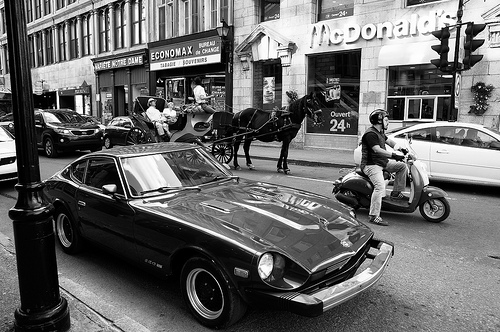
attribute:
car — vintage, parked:
[39, 140, 393, 328]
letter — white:
[330, 27, 343, 44]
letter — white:
[309, 25, 333, 49]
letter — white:
[343, 22, 360, 42]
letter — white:
[376, 21, 395, 41]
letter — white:
[392, 12, 420, 39]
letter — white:
[354, 18, 375, 42]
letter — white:
[180, 43, 195, 61]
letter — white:
[170, 41, 194, 69]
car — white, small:
[355, 114, 497, 195]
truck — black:
[5, 103, 105, 156]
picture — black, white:
[0, 1, 498, 330]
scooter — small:
[329, 146, 452, 234]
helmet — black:
[366, 106, 386, 127]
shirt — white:
[140, 106, 180, 141]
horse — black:
[221, 109, 327, 165]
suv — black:
[39, 100, 125, 170]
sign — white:
[366, 22, 456, 86]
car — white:
[358, 106, 497, 243]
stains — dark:
[381, 295, 441, 310]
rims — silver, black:
[129, 238, 285, 328]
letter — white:
[146, 57, 178, 71]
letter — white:
[154, 47, 156, 60]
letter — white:
[159, 55, 207, 65]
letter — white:
[162, 51, 185, 73]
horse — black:
[227, 76, 339, 186]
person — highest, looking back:
[181, 65, 217, 110]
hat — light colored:
[147, 90, 168, 108]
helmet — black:
[369, 112, 390, 134]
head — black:
[301, 69, 336, 144]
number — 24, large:
[329, 109, 348, 149]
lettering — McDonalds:
[287, 0, 494, 90]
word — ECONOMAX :
[136, 40, 197, 62]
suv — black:
[18, 96, 132, 170]